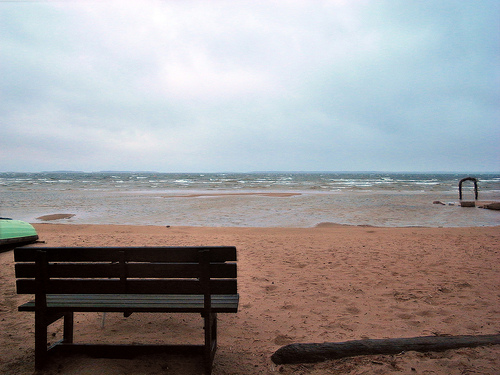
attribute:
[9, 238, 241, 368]
bench — brown, small, wooden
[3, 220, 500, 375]
beach — wet, dry, sandy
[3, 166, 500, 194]
ocean — green blue, clear, blue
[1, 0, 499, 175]
sky — cloudy, blue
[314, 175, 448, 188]
wave — large, foamy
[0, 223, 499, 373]
sand — tan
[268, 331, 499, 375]
log — brown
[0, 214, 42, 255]
boat — turned over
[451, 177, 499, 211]
structure — rock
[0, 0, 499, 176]
clouds — white